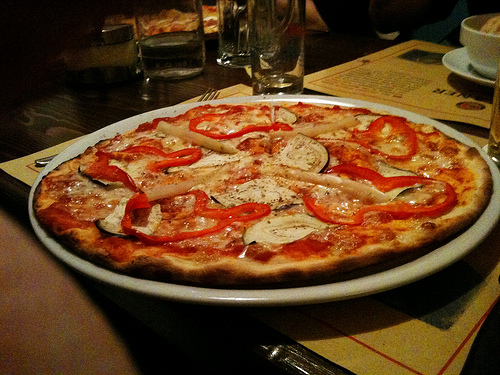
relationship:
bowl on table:
[453, 21, 497, 88] [151, 3, 499, 98]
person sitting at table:
[276, 2, 427, 47] [0, 28, 480, 373]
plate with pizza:
[56, 49, 472, 342] [84, 104, 440, 294]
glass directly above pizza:
[235, 0, 337, 107] [107, 93, 489, 295]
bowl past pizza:
[453, 21, 497, 88] [38, 99, 498, 281]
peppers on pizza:
[94, 110, 456, 242] [38, 99, 498, 281]